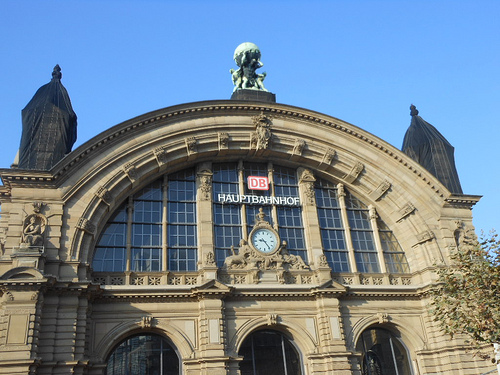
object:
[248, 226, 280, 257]
clock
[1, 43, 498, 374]
building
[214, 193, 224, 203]
h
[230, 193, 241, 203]
u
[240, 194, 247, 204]
p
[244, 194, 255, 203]
t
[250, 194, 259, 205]
b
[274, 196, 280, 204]
n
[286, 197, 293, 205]
o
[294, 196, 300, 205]
f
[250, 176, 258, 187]
d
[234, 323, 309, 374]
opening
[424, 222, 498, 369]
tree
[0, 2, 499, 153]
sky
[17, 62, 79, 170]
covering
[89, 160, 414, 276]
window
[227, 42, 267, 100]
statue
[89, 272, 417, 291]
railing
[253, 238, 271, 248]
hands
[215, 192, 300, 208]
name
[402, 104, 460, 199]
tower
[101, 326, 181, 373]
doorway